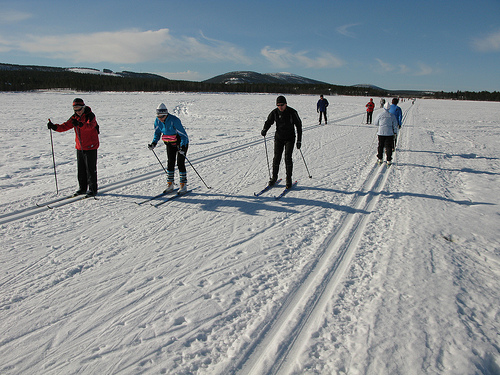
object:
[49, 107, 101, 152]
coat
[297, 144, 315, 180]
pole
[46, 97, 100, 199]
person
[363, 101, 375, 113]
red jacket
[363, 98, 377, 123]
person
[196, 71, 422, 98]
mountains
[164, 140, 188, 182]
pants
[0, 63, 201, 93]
mountain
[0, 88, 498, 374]
snow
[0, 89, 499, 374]
ground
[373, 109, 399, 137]
jacket